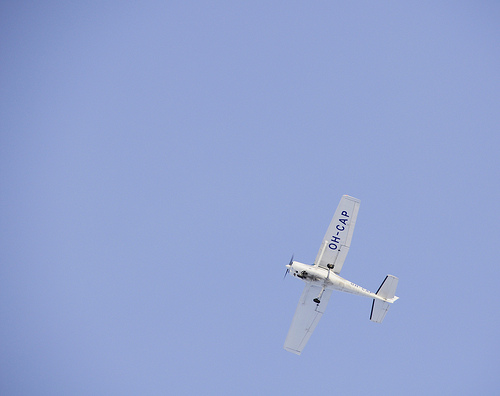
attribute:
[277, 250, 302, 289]
propellor — turning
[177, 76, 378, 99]
sky — blue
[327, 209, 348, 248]
oh-cap — blue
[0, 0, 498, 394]
sky — blue, clear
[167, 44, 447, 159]
sky — blue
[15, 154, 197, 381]
sky — clear, blue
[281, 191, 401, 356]
plane — white, small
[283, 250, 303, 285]
propeller — blue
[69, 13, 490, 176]
sky — blue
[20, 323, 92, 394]
clouds — white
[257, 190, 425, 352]
plane — small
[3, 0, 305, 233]
sky — blue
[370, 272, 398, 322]
tail — black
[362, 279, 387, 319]
stripe — blue